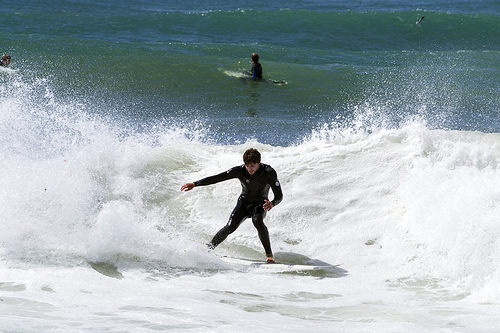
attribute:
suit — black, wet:
[205, 174, 286, 242]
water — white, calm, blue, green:
[49, 108, 450, 305]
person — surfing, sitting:
[185, 143, 317, 282]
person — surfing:
[220, 50, 287, 83]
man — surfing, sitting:
[237, 55, 279, 78]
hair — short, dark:
[245, 150, 255, 159]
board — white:
[210, 242, 388, 286]